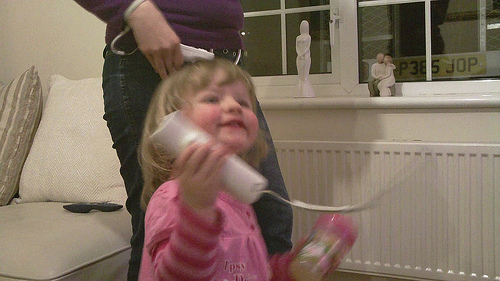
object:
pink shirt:
[136, 177, 293, 281]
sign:
[394, 51, 488, 80]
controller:
[178, 43, 216, 61]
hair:
[140, 57, 268, 211]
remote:
[63, 202, 124, 213]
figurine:
[368, 52, 397, 97]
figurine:
[294, 19, 316, 98]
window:
[241, 0, 330, 78]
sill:
[255, 93, 500, 110]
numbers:
[398, 57, 480, 75]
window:
[354, 0, 500, 83]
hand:
[293, 236, 342, 274]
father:
[70, 0, 295, 281]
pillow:
[12, 72, 131, 210]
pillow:
[0, 63, 43, 204]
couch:
[0, 64, 129, 281]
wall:
[0, 0, 82, 52]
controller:
[150, 110, 268, 204]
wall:
[353, 107, 500, 140]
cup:
[283, 213, 360, 281]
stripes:
[156, 197, 226, 281]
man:
[368, 53, 386, 97]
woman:
[377, 55, 396, 97]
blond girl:
[133, 59, 341, 281]